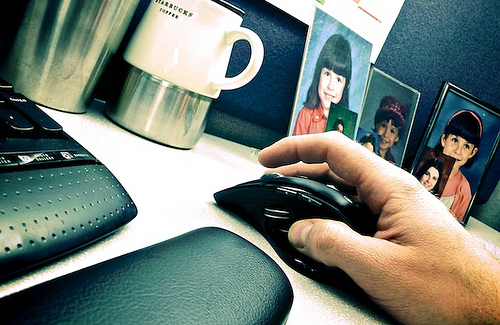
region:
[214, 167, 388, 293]
black computer mouse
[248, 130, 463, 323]
hand of the person using the mouse.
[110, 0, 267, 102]
white mug with words on it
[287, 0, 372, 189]
picture of a girl wearing red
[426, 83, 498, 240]
picture of a girl wearing pink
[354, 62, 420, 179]
picture of a girl wearing purple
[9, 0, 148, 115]
metal cup on the desk.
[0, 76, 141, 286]
keyboard on the desk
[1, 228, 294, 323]
wrist rest on the desk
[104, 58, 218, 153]
metal cup under the mug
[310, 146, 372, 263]
he has his hand on the mouse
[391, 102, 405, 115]
the hat is purple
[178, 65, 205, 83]
the cup is white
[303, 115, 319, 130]
the shirt is reddish pink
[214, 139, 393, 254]
wireless black mouse on table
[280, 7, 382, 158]
child's picture on desk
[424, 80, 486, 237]
child's picture on desk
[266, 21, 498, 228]
family pictures on desk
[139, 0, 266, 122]
white coffee mug on desk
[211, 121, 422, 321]
hand holding wireless mouse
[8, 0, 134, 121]
metal silver coffee mug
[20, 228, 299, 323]
arm rest in front of keyboard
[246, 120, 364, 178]
the index finger of a man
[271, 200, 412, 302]
the thumb of a man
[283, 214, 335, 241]
the fingernail of a man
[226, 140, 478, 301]
the hand of a man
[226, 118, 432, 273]
a black mouse on a table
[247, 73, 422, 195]
fingers on a hand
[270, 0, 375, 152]
a picture on a desk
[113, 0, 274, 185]
a cup on a desk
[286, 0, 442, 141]
a picture of a girl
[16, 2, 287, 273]
a keyboard on a desk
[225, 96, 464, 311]
person is holding a mouse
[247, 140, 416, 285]
person is holding a mouse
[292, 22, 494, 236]
pictures on the desk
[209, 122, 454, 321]
A hand on a computer mouse.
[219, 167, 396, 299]
A black computer mouse.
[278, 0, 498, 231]
Family pictures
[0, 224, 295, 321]
dark green wrist protector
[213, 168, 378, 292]
black mouse with center roller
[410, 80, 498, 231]
picture of young girl with black bangs and pink headband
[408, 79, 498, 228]
black framed picture of young girl with black bangs and pink headband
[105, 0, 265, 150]
white and silver coffee cup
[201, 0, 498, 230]
blue wall behind a white desk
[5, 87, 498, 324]
white desk top next to a blue wall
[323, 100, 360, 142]
unframed small photograph with a green background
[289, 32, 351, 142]
young girl with black bangs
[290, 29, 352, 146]
young girl wearing an orange shirt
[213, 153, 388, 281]
man holding a black mouse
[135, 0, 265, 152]
coffee mug on the desk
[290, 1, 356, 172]
picture of girl on the desk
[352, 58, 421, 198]
picture of girl on the desk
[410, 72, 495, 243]
picture of girl on the desk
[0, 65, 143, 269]
Keyboard on the desk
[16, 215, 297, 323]
wrist rest on the desk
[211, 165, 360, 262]
person holding a black mouse